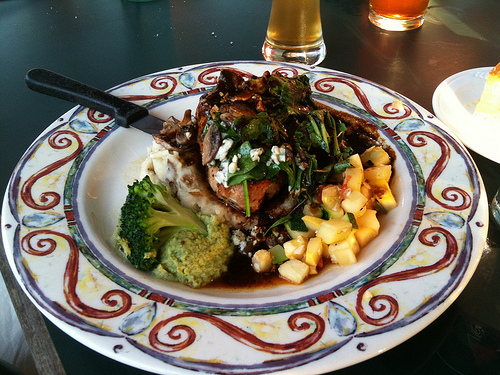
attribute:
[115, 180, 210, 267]
broccoli — overcooked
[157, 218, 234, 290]
broccoli — overcooked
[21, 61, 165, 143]
knife — black-handled, steak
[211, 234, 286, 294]
sauce — brown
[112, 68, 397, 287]
mixture — veggie, cheese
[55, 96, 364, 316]
round plate — brown-patterned, blue-patterned, green-patterned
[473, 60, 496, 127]
corn bread — square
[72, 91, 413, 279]
meal — hearty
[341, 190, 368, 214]
corn — well-seasoned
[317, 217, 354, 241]
potato — piece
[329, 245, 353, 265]
potato — piece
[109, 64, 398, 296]
meal — healthy looking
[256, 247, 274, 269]
potatoe — piece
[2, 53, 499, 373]
designs — blue, red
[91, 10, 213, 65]
tabletop — shiny, black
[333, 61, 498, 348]
scrolls — red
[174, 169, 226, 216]
potatoes — lumpy, mashed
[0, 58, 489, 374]
plate — white, designed, plain, multi colored